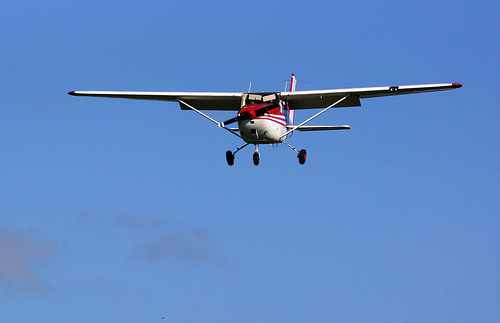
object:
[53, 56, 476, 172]
airplane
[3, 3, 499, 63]
sky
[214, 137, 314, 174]
landing gear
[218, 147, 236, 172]
wheel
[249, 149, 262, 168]
wheel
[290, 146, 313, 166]
wheel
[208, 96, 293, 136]
propeller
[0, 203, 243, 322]
cloud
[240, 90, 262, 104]
window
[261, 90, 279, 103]
window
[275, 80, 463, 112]
wing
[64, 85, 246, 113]
wing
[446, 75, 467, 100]
tip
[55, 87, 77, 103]
tip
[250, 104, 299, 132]
stripe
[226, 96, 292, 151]
nose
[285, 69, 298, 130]
tail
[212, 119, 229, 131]
stripe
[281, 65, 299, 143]
stripe